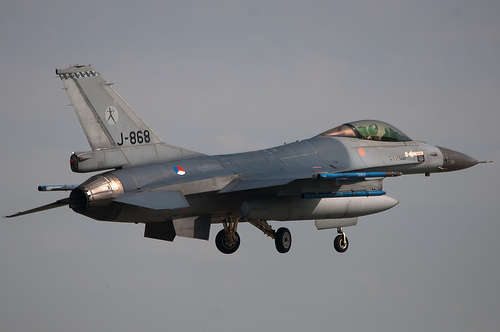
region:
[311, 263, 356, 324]
the sky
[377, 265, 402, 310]
the sky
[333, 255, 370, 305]
the sky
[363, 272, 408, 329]
the sky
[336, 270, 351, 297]
the sky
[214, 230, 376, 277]
the plane has wheels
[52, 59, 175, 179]
the plane has a verticle stabilizer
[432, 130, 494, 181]
the plane has a nose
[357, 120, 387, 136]
the pilot is in the plane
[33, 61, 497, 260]
the plane is flying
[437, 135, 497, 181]
the nose of the plane is black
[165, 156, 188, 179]
the plane has a logo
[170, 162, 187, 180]
the logo is red white and blue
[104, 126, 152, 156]
the letter and numbers are painted in black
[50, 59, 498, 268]
the plane is gray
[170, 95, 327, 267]
a jet in the sky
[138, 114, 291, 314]
a jet in the sky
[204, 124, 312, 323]
a jet in the sky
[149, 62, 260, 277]
a jet in the sky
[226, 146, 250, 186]
a jet plane in the sky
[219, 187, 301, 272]
a jet plane in the sky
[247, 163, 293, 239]
a jet plane in the sky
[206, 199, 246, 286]
a jet plane in the sky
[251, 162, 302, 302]
a jet plane in the sky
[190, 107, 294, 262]
a jet plane in the sky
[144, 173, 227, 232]
a jet plane in the sky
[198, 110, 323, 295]
a jet plane in the sky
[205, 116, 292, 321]
a jet plane in the sky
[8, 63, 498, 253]
the plane in mid air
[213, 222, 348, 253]
the wheels under the plane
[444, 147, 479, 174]
the nose on the plane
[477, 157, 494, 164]
the point on the nose of the plane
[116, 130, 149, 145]
the letter and numbers on the plane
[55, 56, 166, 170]
the tail of the plane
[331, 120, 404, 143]
the cockpit of the plane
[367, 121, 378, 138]
the person in the plane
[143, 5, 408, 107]
the gray sky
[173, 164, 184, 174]
the red, blue and white circle on the plane